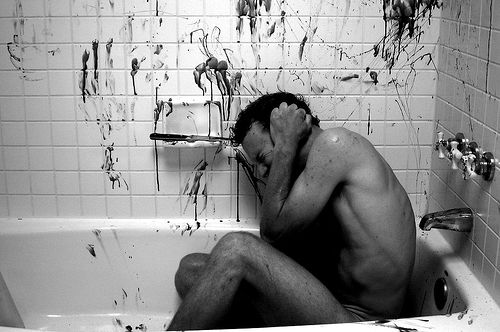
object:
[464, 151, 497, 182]
faucet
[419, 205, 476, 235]
faucet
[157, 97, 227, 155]
soap dish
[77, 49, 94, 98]
blood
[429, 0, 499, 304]
walls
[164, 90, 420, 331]
man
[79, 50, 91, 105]
prints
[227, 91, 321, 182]
head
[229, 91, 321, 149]
hair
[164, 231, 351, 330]
legs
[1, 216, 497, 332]
tub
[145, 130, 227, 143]
knife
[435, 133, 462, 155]
faucet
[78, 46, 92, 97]
blood spatter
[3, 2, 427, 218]
wall